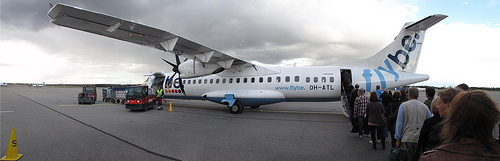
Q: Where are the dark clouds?
A: In the sky.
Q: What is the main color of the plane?
A: White.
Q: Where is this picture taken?
A: Airport.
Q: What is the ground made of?
A: Concrete.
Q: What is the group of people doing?
A: Getting ready to board the train.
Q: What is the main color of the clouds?
A: White.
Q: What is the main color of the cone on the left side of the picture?
A: Yellow.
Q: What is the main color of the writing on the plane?
A: Blue.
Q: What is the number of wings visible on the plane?
A: 1.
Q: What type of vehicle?
A: Airplane.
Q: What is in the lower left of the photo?
A: Safety Cone.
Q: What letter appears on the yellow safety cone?
A: S.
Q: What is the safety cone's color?
A: Yellow.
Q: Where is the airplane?
A: Tarmac.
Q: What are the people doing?
A: Boarding the plane.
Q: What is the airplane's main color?
A: White.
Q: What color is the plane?
A: White, blue, and black.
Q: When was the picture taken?
A: Daytime.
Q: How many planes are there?
A: One.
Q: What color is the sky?
A: Blue.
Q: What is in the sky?
A: Clouds.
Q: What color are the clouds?
A: White.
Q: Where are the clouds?
A: In the sky.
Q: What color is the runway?
A: Gray.